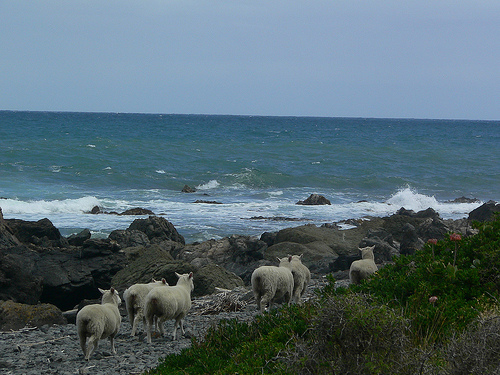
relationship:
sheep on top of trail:
[76, 285, 123, 358] [1, 243, 350, 372]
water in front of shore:
[2, 112, 500, 200] [3, 186, 500, 241]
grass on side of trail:
[143, 216, 500, 373] [1, 243, 350, 372]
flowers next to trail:
[427, 233, 462, 268] [1, 243, 350, 372]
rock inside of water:
[297, 192, 330, 203] [2, 112, 500, 200]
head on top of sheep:
[99, 288, 122, 308] [76, 285, 123, 358]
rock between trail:
[0, 200, 499, 307] [1, 243, 350, 372]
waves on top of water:
[1, 184, 499, 219] [2, 112, 500, 200]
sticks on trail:
[197, 295, 244, 314] [1, 243, 350, 372]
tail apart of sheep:
[84, 312, 94, 322] [76, 285, 123, 358]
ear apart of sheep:
[109, 289, 115, 296] [76, 285, 123, 358]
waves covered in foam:
[1, 184, 499, 219] [1, 178, 481, 243]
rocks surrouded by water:
[87, 184, 481, 221] [2, 112, 500, 200]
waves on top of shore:
[1, 184, 499, 219] [3, 186, 500, 241]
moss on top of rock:
[4, 303, 58, 321] [0, 300, 68, 331]